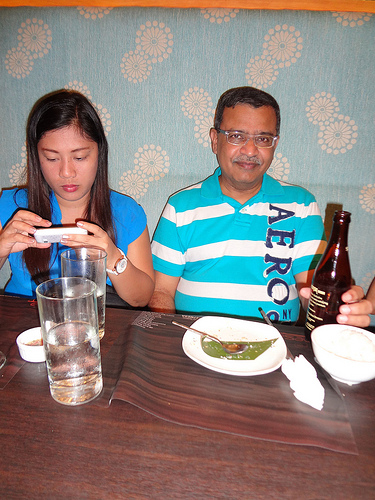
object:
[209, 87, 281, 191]
head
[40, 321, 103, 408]
water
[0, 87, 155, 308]
girl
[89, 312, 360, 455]
cloth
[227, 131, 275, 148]
glasses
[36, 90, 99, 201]
head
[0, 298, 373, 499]
table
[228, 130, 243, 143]
eye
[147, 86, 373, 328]
man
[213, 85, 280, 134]
hair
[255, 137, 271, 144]
eye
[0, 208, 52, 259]
hand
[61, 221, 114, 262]
hand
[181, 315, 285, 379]
dinner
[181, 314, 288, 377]
plate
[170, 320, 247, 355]
spoon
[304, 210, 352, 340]
glass bottle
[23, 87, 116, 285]
hair